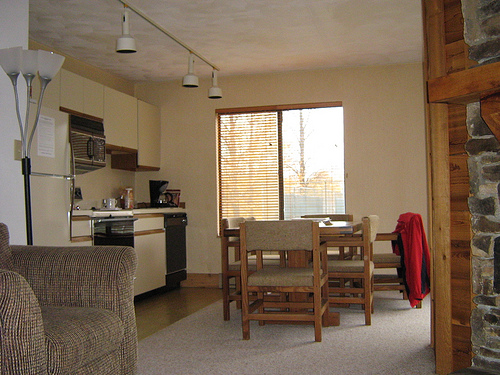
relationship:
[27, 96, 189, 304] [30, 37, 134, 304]
kitchenette on wall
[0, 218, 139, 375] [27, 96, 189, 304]
chair in front of kitchenette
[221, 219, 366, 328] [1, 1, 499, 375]
table across room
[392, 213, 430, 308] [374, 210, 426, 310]
jacket on chair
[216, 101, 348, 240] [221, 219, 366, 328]
window behind table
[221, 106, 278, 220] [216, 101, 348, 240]
blinds are on window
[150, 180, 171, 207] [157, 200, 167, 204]
pot used for coffee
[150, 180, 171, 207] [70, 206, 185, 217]
pot on counter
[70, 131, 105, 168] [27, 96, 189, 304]
microwave in kitchenette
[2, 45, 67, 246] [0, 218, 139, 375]
lamp behind chair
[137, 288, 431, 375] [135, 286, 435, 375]
carpet on floor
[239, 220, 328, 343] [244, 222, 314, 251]
chair has back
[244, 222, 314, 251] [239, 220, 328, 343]
back on chair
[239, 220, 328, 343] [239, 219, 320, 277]
chair has top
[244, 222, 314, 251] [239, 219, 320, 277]
back on top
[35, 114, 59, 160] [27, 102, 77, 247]
paper on fridge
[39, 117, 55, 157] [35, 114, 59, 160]
lettering on paper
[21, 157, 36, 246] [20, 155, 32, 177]
pole has top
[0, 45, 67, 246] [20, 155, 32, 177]
lamp on top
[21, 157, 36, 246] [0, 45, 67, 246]
pole holding lamp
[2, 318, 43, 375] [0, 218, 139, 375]
pattern on couch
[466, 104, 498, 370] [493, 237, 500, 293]
place for fire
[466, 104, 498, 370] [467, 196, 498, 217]
place made from brick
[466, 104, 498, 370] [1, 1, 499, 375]
place in house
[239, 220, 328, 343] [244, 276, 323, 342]
chair has bottom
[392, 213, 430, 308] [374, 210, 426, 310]
jacket hanging from chair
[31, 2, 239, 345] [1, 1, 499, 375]
kitchen in room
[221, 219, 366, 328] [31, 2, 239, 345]
table in kitchen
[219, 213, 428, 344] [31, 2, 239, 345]
chairs are in kitchen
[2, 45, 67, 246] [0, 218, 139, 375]
type beside chair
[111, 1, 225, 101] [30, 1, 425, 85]
style on ceiling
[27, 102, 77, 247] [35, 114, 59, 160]
fridge has note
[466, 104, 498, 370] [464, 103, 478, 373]
place has edge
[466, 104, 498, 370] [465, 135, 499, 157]
place made of stone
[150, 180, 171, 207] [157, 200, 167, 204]
pot for coffee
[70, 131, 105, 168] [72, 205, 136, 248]
microwave over stove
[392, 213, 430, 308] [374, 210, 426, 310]
jacket hanging on chair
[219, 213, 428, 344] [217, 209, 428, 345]
chairs are in set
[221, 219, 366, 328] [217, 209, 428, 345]
table in set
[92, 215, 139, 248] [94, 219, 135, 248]
oven has door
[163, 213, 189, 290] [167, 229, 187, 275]
dishwasher made of metal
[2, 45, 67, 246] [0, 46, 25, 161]
lamp has head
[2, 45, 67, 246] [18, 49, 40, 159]
lamp has head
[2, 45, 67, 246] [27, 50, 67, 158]
lamp has head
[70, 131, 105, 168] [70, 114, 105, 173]
microwave made of steel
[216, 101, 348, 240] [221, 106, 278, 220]
window has blinds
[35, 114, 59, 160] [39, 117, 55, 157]
paper has writing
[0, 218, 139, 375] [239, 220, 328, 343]
chair made of chair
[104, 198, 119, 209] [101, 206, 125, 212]
cup on plate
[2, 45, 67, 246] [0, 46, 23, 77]
lamp has bulb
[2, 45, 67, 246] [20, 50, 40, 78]
lamp has bulb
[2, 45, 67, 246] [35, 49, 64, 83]
lamp has bulb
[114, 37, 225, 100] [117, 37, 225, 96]
lights in a row